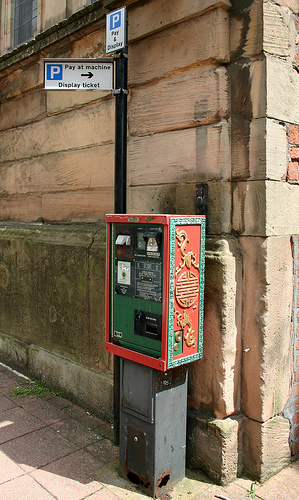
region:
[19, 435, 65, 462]
cement tile on the ground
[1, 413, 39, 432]
cement tile on the ground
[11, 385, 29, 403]
cement tile on the ground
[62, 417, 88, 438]
cement tile on the ground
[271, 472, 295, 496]
cement tile on the ground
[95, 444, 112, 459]
cement tile on the ground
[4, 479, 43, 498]
cement tile on the ground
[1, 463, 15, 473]
cement tile on the ground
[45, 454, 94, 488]
cement tile on the ground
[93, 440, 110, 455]
cement tile on the ground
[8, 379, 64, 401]
Weeds growing in the spaces between the stones of a sidewalk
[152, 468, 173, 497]
Big rusted hole on a grey metal box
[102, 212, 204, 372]
Green and red parking ticket machine with places to retrieve money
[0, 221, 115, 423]
Dirty cement wall with patches of green moss growing on it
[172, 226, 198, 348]
Gold Asian decor on a red background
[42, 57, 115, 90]
Sign with a P indicating parking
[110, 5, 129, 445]
Black metal pole against a building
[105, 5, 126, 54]
A sign that has the words Pay & Display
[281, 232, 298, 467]
Red brick wall with grey cement in spaces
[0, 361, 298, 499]
Sidewalk made of large square red bricks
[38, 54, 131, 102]
A blue and white sign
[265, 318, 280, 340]
Part of the wall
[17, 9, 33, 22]
Part of the window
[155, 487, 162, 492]
Part of the rust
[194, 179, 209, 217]
A black spot on the wall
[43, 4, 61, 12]
Part of the building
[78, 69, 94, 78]
A direction arrow on the sign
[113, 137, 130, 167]
Part of the pole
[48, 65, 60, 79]
The letter is white.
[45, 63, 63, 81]
The square is blue.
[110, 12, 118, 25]
The letter is white.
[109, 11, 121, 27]
The square is blue.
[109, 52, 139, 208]
The pole is black.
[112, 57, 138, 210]
The pole is metal.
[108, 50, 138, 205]
The pole is straight.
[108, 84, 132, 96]
The pole has a clamp.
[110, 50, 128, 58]
The pole has a clamp.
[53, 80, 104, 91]
The letters are black.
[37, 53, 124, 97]
a black and white sign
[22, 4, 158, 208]
signs on a pole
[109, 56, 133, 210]
the pole is black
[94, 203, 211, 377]
a red and green machine